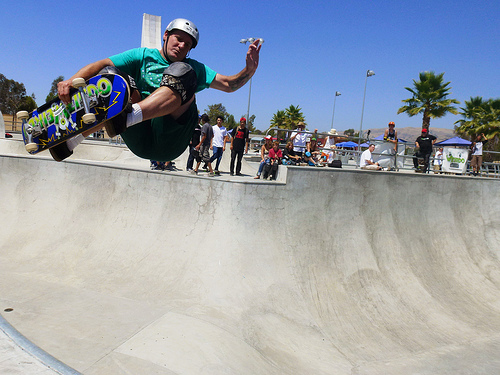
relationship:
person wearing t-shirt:
[203, 113, 231, 174] [210, 122, 228, 148]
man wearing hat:
[228, 115, 250, 176] [238, 116, 244, 122]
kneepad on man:
[163, 59, 198, 102] [47, 16, 263, 163]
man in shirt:
[47, 16, 263, 163] [108, 44, 212, 110]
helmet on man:
[163, 18, 200, 48] [47, 16, 263, 163]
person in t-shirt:
[203, 113, 231, 174] [210, 122, 228, 148]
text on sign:
[445, 153, 466, 164] [440, 145, 470, 178]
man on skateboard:
[47, 16, 263, 163] [12, 71, 131, 154]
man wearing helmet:
[47, 16, 263, 163] [163, 18, 200, 48]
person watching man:
[203, 113, 231, 174] [47, 16, 263, 163]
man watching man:
[228, 115, 250, 176] [47, 16, 263, 163]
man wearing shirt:
[47, 16, 263, 163] [108, 44, 212, 110]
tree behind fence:
[397, 68, 460, 159] [261, 127, 498, 184]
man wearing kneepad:
[47, 16, 263, 163] [163, 59, 198, 102]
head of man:
[159, 19, 200, 60] [47, 16, 263, 163]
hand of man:
[246, 40, 261, 74] [47, 16, 263, 163]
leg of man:
[129, 60, 199, 138] [47, 16, 263, 163]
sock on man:
[124, 102, 143, 132] [47, 16, 263, 163]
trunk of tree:
[420, 111, 433, 135] [397, 68, 460, 159]